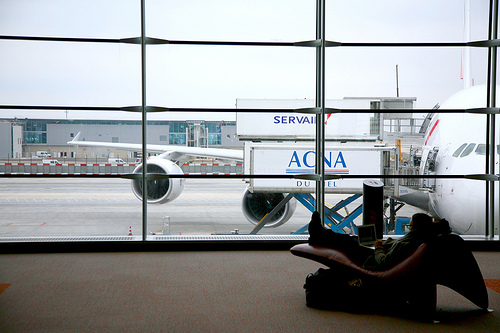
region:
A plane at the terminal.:
[381, 85, 498, 223]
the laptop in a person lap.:
[352, 211, 388, 248]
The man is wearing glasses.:
[398, 210, 416, 229]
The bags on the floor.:
[296, 266, 381, 326]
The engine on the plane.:
[117, 140, 192, 205]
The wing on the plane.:
[62, 123, 232, 193]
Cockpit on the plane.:
[446, 138, 498, 176]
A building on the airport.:
[10, 102, 245, 169]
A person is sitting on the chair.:
[293, 196, 460, 277]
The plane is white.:
[403, 76, 493, 216]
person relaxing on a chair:
[293, 206, 495, 331]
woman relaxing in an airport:
[282, 200, 492, 329]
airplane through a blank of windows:
[53, 71, 499, 235]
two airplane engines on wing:
[125, 136, 306, 231]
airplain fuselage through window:
[415, 83, 490, 230]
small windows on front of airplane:
[444, 138, 496, 163]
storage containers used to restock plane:
[224, 88, 401, 209]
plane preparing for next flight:
[51, 75, 499, 229]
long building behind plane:
[6, 93, 438, 195]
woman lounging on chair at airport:
[287, 192, 492, 321]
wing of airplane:
[63, 132, 252, 165]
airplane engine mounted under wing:
[126, 154, 190, 209]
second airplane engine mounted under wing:
[243, 183, 296, 229]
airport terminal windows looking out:
[4, 5, 499, 233]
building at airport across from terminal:
[6, 96, 248, 170]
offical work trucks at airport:
[37, 150, 66, 171]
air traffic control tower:
[375, 61, 441, 150]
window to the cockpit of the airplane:
[454, 138, 498, 167]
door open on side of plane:
[423, 147, 440, 196]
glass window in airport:
[144, 176, 315, 233]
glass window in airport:
[1, 177, 142, 235]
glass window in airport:
[1, 108, 143, 173]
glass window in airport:
[146, 110, 314, 171]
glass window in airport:
[324, 113, 486, 170]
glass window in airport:
[325, 46, 485, 106]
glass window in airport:
[146, 43, 314, 106]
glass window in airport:
[0, 40, 142, 107]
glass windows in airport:
[0, 35, 492, 242]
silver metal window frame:
[313, 3, 330, 40]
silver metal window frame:
[486, 3, 498, 40]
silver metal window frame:
[138, 3, 148, 35]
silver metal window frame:
[1, 32, 136, 47]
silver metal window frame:
[146, 34, 319, 50]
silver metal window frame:
[325, 35, 485, 48]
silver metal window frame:
[3, 102, 141, 116]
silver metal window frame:
[144, 104, 318, 119]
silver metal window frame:
[323, 105, 486, 114]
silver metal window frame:
[146, 170, 317, 182]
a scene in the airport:
[0, 12, 495, 323]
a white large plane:
[50, 80, 495, 235]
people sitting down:
[277, 195, 497, 320]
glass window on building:
[0, 174, 144, 239]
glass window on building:
[144, 171, 314, 239]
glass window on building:
[324, 175, 499, 240]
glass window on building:
[323, 112, 485, 182]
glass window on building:
[144, 38, 319, 110]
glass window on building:
[322, 44, 489, 108]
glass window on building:
[144, 0, 319, 42]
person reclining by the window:
[306, 190, 433, 264]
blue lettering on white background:
[267, 109, 347, 170]